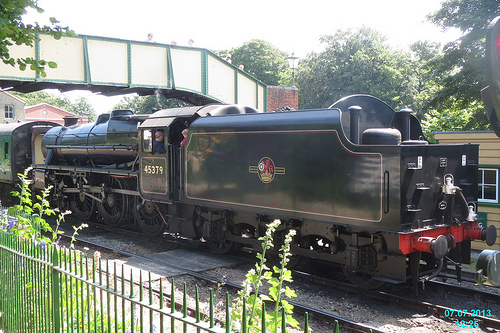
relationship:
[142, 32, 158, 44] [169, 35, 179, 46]
people standing near people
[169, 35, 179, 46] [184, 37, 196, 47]
people standing near people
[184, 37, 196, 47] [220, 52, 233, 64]
people standing near people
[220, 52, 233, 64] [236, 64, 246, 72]
people standing near people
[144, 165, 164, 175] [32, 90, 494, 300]
45379 on train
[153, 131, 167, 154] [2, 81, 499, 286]
driver in train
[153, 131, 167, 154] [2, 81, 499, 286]
driver leaning on train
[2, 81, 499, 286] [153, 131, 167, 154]
train moving driver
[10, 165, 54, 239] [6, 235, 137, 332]
green leafy are near fence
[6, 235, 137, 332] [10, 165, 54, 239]
fence are near green leafy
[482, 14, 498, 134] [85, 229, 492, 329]
light are near tracks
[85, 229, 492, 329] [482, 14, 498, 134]
tracks are near light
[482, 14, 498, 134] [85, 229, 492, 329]
light above tracks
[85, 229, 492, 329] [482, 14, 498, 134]
tracks are below light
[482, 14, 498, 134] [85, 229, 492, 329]
light to right of tracks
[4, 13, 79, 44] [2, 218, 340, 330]
tree limb near fence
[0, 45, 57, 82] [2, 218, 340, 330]
tree limb near fence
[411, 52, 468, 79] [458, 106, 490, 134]
tree limb near tree limb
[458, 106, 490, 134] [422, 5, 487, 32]
tree limb near tree limb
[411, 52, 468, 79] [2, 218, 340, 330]
tree limb on other side of fence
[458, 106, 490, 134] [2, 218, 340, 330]
tree limb on other side of fence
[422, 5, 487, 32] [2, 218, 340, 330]
tree limb on other side of fence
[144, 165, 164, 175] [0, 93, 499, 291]
45379 on train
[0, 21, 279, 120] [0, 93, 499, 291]
bridge over train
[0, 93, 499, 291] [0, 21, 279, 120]
train under bridge